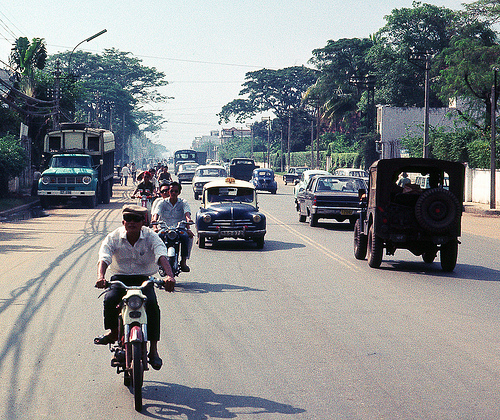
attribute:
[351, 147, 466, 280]
car — old, brown, antique looking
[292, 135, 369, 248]
sedan — brown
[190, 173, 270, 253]
taxi — old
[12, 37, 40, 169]
tree — green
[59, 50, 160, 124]
tree — green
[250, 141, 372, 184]
hedge — long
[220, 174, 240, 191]
sign — yellow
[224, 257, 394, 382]
ground — grey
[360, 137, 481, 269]
jeep — old, military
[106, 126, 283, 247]
car — blue, white colored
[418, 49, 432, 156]
pole — tall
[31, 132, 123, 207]
truck — blue 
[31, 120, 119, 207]
truck — green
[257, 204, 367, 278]
line — yellow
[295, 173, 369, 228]
sedan — old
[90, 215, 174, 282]
shirt — white